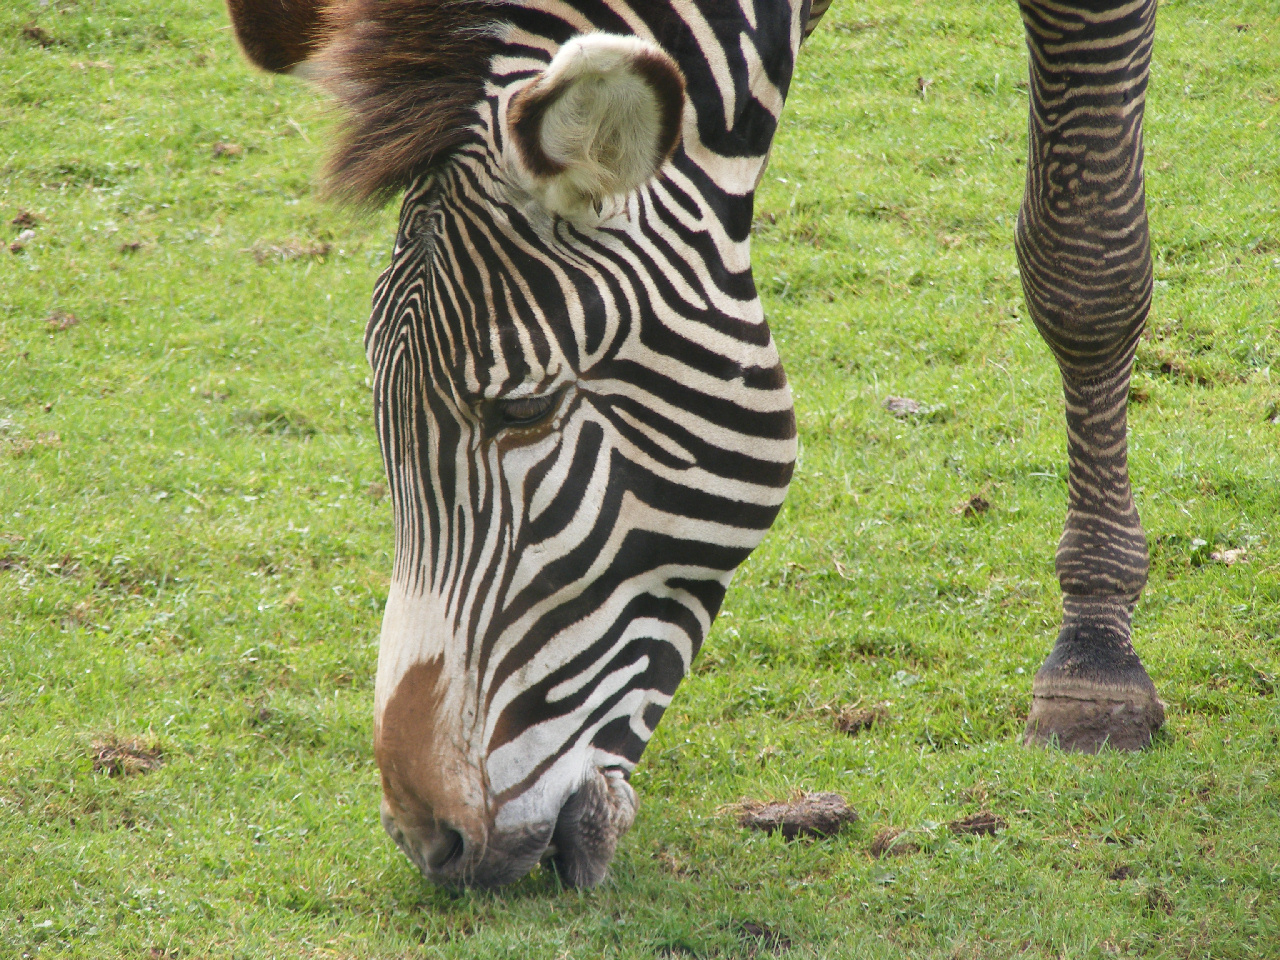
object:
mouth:
[368, 714, 641, 904]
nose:
[374, 664, 481, 897]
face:
[374, 202, 795, 887]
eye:
[498, 390, 564, 431]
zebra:
[361, 37, 798, 899]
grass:
[758, 796, 857, 835]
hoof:
[1009, 650, 1174, 755]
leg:
[985, 72, 1272, 567]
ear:
[486, 34, 683, 215]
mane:
[309, 3, 478, 207]